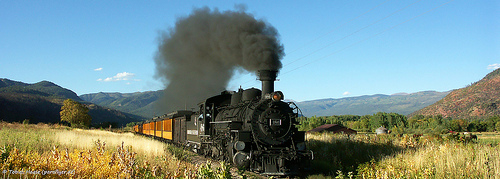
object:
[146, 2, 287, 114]
smoke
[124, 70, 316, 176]
train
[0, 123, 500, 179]
ground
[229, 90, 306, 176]
front view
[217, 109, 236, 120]
black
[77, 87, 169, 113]
mountains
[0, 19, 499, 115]
background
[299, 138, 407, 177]
shadow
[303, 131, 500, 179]
grass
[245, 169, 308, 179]
track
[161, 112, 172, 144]
car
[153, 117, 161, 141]
cars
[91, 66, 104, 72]
clouds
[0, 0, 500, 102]
sky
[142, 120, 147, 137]
train car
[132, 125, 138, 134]
cargo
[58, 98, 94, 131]
tree